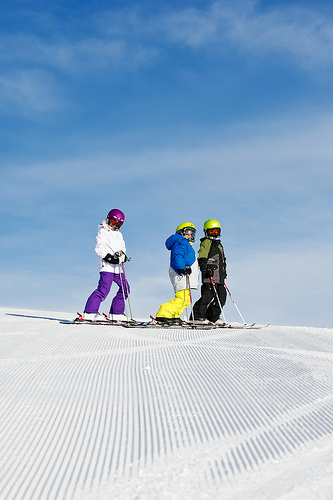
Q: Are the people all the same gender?
A: No, they are both male and female.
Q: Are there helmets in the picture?
A: Yes, there is a helmet.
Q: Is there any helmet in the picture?
A: Yes, there is a helmet.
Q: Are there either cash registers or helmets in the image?
A: Yes, there is a helmet.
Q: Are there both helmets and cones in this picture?
A: No, there is a helmet but no cones.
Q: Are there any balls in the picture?
A: No, there are no balls.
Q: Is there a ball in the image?
A: No, there are no balls.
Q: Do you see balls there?
A: No, there are no balls.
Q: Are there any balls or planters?
A: No, there are no balls or planters.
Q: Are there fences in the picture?
A: No, there are no fences.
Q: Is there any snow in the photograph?
A: Yes, there is snow.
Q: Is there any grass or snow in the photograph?
A: Yes, there is snow.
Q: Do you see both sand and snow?
A: No, there is snow but no sand.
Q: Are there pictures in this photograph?
A: No, there are no pictures.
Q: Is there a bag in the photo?
A: No, there are no bags.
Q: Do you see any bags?
A: No, there are no bags.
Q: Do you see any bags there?
A: No, there are no bags.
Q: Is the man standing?
A: Yes, the man is standing.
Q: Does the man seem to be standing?
A: Yes, the man is standing.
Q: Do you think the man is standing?
A: Yes, the man is standing.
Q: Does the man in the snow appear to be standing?
A: Yes, the man is standing.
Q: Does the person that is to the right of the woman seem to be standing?
A: Yes, the man is standing.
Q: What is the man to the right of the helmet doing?
A: The man is standing.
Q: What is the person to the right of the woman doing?
A: The man is standing.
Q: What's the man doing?
A: The man is standing.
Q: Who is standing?
A: The man is standing.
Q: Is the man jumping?
A: No, the man is standing.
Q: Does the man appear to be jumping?
A: No, the man is standing.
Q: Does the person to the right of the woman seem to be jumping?
A: No, the man is standing.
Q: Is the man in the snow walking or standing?
A: The man is standing.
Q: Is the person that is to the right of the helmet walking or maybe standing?
A: The man is standing.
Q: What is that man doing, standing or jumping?
A: The man is standing.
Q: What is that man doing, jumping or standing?
A: The man is standing.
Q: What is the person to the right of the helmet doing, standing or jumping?
A: The man is standing.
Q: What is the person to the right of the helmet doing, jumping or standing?
A: The man is standing.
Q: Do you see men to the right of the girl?
A: Yes, there is a man to the right of the girl.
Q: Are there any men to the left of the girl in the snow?
A: No, the man is to the right of the girl.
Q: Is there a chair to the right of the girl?
A: No, there is a man to the right of the girl.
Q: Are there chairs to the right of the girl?
A: No, there is a man to the right of the girl.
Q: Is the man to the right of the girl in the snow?
A: Yes, the man is to the right of the girl.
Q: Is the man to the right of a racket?
A: No, the man is to the right of the girl.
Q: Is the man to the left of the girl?
A: No, the man is to the right of the girl.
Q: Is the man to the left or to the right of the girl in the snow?
A: The man is to the right of the girl.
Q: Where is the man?
A: The man is in the snow.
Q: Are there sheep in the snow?
A: No, there is a man in the snow.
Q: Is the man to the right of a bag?
A: No, the man is to the right of the helmet.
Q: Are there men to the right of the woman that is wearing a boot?
A: Yes, there is a man to the right of the woman.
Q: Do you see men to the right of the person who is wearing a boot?
A: Yes, there is a man to the right of the woman.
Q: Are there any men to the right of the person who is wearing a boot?
A: Yes, there is a man to the right of the woman.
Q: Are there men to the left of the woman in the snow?
A: No, the man is to the right of the woman.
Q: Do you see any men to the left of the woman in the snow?
A: No, the man is to the right of the woman.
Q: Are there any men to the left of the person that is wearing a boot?
A: No, the man is to the right of the woman.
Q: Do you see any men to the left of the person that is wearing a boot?
A: No, the man is to the right of the woman.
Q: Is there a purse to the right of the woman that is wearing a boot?
A: No, there is a man to the right of the woman.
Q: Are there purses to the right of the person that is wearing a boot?
A: No, there is a man to the right of the woman.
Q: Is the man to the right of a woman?
A: Yes, the man is to the right of a woman.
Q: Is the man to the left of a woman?
A: No, the man is to the right of a woman.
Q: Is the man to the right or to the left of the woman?
A: The man is to the right of the woman.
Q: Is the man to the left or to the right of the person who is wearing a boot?
A: The man is to the right of the woman.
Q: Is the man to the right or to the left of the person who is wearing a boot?
A: The man is to the right of the woman.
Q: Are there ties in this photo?
A: No, there are no ties.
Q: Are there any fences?
A: No, there are no fences.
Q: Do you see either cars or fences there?
A: No, there are no fences or cars.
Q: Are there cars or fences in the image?
A: No, there are no fences or cars.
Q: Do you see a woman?
A: Yes, there is a woman.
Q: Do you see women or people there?
A: Yes, there is a woman.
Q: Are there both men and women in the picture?
A: Yes, there are both a woman and a man.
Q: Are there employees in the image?
A: No, there are no employees.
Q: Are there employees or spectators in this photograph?
A: No, there are no employees or spectators.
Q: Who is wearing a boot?
A: The woman is wearing a boot.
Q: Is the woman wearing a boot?
A: Yes, the woman is wearing a boot.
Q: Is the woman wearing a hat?
A: No, the woman is wearing a boot.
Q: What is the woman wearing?
A: The woman is wearing a boot.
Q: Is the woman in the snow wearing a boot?
A: Yes, the woman is wearing a boot.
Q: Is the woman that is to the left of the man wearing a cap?
A: No, the woman is wearing a boot.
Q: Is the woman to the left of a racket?
A: No, the woman is to the left of the helmet.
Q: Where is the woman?
A: The woman is in the snow.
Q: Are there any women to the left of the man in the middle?
A: Yes, there is a woman to the left of the man.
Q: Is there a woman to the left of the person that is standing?
A: Yes, there is a woman to the left of the man.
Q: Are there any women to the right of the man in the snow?
A: No, the woman is to the left of the man.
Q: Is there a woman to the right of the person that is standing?
A: No, the woman is to the left of the man.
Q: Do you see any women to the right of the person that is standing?
A: No, the woman is to the left of the man.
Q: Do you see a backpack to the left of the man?
A: No, there is a woman to the left of the man.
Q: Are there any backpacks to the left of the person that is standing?
A: No, there is a woman to the left of the man.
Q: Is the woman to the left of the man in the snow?
A: Yes, the woman is to the left of the man.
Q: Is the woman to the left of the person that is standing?
A: Yes, the woman is to the left of the man.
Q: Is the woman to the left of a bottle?
A: No, the woman is to the left of the man.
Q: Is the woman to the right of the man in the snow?
A: No, the woman is to the left of the man.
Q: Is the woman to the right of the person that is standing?
A: No, the woman is to the left of the man.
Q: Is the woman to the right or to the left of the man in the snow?
A: The woman is to the left of the man.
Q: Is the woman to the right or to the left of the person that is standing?
A: The woman is to the left of the man.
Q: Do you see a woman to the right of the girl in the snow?
A: Yes, there is a woman to the right of the girl.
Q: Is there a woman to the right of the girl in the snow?
A: Yes, there is a woman to the right of the girl.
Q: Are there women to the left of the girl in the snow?
A: No, the woman is to the right of the girl.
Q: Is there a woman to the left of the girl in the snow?
A: No, the woman is to the right of the girl.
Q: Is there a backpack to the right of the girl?
A: No, there is a woman to the right of the girl.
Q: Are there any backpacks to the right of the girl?
A: No, there is a woman to the right of the girl.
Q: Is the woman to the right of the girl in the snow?
A: Yes, the woman is to the right of the girl.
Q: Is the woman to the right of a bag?
A: No, the woman is to the right of the girl.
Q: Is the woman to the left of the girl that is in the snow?
A: No, the woman is to the right of the girl.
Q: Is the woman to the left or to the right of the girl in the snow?
A: The woman is to the right of the girl.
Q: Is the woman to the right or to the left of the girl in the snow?
A: The woman is to the right of the girl.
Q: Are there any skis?
A: Yes, there are skis.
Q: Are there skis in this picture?
A: Yes, there are skis.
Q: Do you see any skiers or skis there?
A: Yes, there are skis.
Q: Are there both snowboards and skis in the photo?
A: No, there are skis but no snowboards.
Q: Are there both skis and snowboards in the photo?
A: No, there are skis but no snowboards.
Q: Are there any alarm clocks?
A: No, there are no alarm clocks.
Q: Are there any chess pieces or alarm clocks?
A: No, there are no alarm clocks or chess pieces.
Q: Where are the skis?
A: The skis are in the snow.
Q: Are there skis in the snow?
A: Yes, there are skis in the snow.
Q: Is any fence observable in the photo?
A: No, there are no fences.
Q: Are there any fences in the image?
A: No, there are no fences.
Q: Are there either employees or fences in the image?
A: No, there are no fences or employees.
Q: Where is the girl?
A: The girl is in the snow.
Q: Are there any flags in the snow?
A: No, there is a girl in the snow.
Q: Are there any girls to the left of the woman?
A: Yes, there is a girl to the left of the woman.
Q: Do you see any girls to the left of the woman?
A: Yes, there is a girl to the left of the woman.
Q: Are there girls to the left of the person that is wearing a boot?
A: Yes, there is a girl to the left of the woman.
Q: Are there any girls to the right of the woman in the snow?
A: No, the girl is to the left of the woman.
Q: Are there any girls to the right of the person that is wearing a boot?
A: No, the girl is to the left of the woman.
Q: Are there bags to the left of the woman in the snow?
A: No, there is a girl to the left of the woman.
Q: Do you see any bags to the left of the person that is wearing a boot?
A: No, there is a girl to the left of the woman.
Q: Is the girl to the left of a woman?
A: Yes, the girl is to the left of a woman.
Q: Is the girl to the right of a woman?
A: No, the girl is to the left of a woman.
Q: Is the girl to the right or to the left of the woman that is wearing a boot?
A: The girl is to the left of the woman.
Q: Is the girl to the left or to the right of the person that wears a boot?
A: The girl is to the left of the woman.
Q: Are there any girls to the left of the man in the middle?
A: Yes, there is a girl to the left of the man.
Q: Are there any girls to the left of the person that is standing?
A: Yes, there is a girl to the left of the man.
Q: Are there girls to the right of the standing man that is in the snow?
A: No, the girl is to the left of the man.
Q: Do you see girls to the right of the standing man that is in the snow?
A: No, the girl is to the left of the man.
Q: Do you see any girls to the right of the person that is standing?
A: No, the girl is to the left of the man.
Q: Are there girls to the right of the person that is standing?
A: No, the girl is to the left of the man.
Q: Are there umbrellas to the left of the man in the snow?
A: No, there is a girl to the left of the man.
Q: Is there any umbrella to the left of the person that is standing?
A: No, there is a girl to the left of the man.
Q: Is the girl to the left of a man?
A: Yes, the girl is to the left of a man.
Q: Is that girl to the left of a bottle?
A: No, the girl is to the left of a man.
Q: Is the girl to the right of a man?
A: No, the girl is to the left of a man.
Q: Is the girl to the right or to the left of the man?
A: The girl is to the left of the man.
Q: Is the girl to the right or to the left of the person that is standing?
A: The girl is to the left of the man.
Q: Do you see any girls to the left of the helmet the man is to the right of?
A: Yes, there is a girl to the left of the helmet.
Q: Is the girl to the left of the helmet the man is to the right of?
A: Yes, the girl is to the left of the helmet.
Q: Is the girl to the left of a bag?
A: No, the girl is to the left of the helmet.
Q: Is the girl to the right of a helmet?
A: No, the girl is to the left of a helmet.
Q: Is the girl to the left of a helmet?
A: Yes, the girl is to the left of a helmet.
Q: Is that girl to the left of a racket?
A: No, the girl is to the left of a helmet.